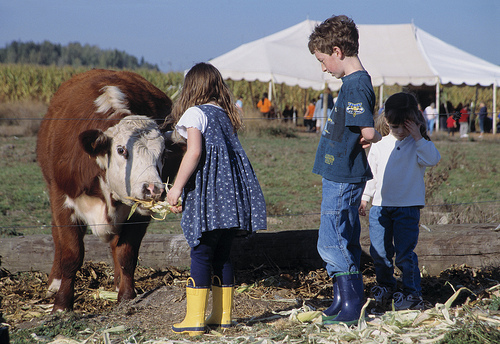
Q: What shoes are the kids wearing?
A: Rain boots.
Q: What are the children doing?
A: Feeding a cow.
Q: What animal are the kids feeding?
A: A cow.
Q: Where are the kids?
A: On a farm.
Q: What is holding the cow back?
A: A fence.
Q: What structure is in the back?
A: A tent.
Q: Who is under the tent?
A: The people.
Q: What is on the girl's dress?
A: Flowers.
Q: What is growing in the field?
A: Corn.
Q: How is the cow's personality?
A: Friendly.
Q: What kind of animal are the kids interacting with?
A: Cow.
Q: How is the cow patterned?
A: Spotted white.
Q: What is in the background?
A: Tent.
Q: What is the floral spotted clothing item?
A: A dress.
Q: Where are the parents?
A: Under the tent.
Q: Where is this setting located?
A: A prairie.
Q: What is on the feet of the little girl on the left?
A: Yellow boots.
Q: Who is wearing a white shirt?
A: The girl on the right.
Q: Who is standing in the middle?
A: A boy.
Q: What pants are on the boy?
A: Jeans.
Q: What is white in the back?
A: A tent.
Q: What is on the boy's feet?
A: Blue boots.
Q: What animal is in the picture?
A: A cow.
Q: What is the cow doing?
A: Being fed by a little girl.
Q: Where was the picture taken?
A: On a farm.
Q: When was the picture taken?
A: Daytime.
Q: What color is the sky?
A: Blue.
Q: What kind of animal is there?
A: A cow.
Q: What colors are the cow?
A: Brown and white.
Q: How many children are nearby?
A: Three.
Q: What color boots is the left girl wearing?
A: Yellow.